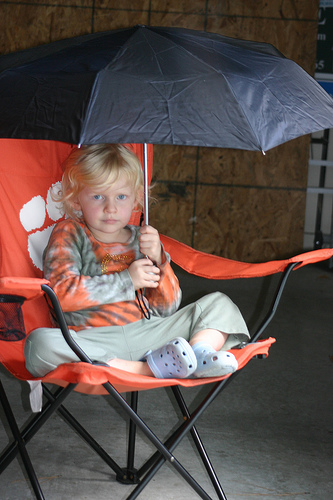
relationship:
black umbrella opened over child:
[3, 29, 332, 156] [24, 146, 252, 383]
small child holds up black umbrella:
[24, 146, 252, 383] [3, 29, 332, 156]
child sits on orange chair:
[24, 146, 252, 383] [3, 136, 331, 499]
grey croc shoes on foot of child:
[145, 337, 240, 380] [24, 146, 252, 383]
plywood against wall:
[3, 6, 316, 269] [3, 3, 332, 271]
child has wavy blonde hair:
[24, 146, 252, 383] [61, 145, 151, 222]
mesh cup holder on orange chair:
[0, 291, 28, 342] [3, 136, 331, 499]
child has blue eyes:
[24, 146, 252, 383] [94, 192, 128, 201]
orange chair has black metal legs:
[3, 136, 331, 499] [4, 259, 304, 499]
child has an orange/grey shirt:
[24, 146, 252, 383] [41, 218, 182, 332]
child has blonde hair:
[24, 146, 252, 383] [61, 145, 151, 222]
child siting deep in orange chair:
[24, 146, 252, 383] [3, 136, 331, 499]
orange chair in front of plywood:
[3, 136, 331, 499] [3, 6, 316, 269]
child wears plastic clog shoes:
[24, 146, 252, 383] [145, 337, 240, 380]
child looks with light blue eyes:
[24, 146, 252, 383] [94, 192, 128, 201]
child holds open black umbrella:
[24, 146, 252, 383] [3, 29, 332, 156]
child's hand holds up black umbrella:
[137, 226, 162, 262] [3, 29, 332, 156]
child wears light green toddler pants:
[24, 146, 252, 383] [26, 291, 252, 375]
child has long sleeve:
[24, 146, 252, 383] [43, 226, 137, 309]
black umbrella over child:
[3, 29, 332, 156] [24, 146, 252, 383]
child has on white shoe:
[24, 146, 252, 383] [146, 337, 199, 379]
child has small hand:
[24, 146, 252, 383] [125, 259, 162, 290]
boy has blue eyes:
[24, 146, 252, 383] [94, 192, 128, 201]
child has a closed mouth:
[24, 146, 252, 383] [100, 216, 119, 225]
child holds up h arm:
[24, 146, 252, 383] [138, 226, 182, 314]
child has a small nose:
[24, 146, 252, 383] [104, 199, 118, 213]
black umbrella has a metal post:
[3, 29, 332, 156] [139, 144, 153, 286]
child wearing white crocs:
[24, 146, 252, 383] [145, 337, 240, 380]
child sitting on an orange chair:
[24, 146, 252, 383] [3, 136, 331, 499]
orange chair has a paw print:
[3, 136, 331, 499] [17, 172, 72, 274]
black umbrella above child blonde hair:
[3, 29, 332, 156] [61, 145, 151, 222]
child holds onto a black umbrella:
[24, 146, 252, 383] [3, 29, 332, 156]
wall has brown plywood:
[3, 3, 332, 271] [3, 6, 316, 269]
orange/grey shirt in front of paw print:
[41, 218, 182, 332] [17, 172, 72, 274]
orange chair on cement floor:
[3, 136, 331, 499] [3, 259, 329, 500]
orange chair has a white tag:
[3, 136, 331, 499] [26, 378, 44, 415]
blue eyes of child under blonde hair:
[94, 192, 128, 201] [61, 145, 151, 222]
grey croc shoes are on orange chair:
[145, 337, 240, 380] [3, 136, 331, 499]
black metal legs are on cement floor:
[4, 259, 304, 499] [3, 259, 329, 500]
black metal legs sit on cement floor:
[4, 259, 304, 499] [3, 259, 329, 500]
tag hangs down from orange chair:
[26, 378, 44, 415] [3, 136, 331, 499]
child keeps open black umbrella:
[24, 146, 252, 383] [3, 29, 332, 156]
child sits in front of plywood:
[24, 146, 252, 383] [3, 6, 316, 269]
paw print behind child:
[17, 172, 72, 274] [24, 146, 252, 383]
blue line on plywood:
[152, 175, 308, 195] [3, 6, 316, 269]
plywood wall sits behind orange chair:
[3, 6, 316, 269] [3, 136, 331, 499]